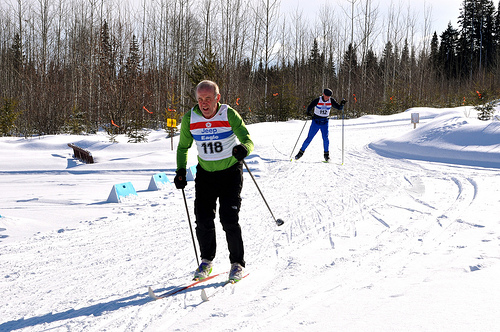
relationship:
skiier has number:
[178, 81, 256, 287] [200, 142, 224, 153]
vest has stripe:
[189, 103, 240, 162] [188, 120, 232, 130]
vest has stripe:
[189, 103, 240, 162] [190, 130, 234, 141]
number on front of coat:
[200, 142, 224, 153] [175, 109, 253, 169]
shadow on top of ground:
[1, 269, 237, 327] [0, 107, 500, 329]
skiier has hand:
[178, 81, 256, 287] [231, 144, 249, 162]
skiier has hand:
[178, 81, 256, 287] [173, 167, 187, 189]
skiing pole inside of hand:
[241, 158, 284, 226] [231, 144, 249, 162]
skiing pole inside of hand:
[181, 187, 200, 267] [173, 167, 187, 189]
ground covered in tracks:
[0, 107, 500, 329] [0, 160, 474, 331]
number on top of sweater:
[200, 142, 224, 153] [175, 109, 253, 169]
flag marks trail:
[110, 120, 121, 128] [0, 108, 488, 332]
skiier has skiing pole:
[178, 81, 256, 287] [241, 158, 284, 226]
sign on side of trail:
[410, 113, 421, 125] [0, 108, 488, 332]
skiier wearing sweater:
[178, 81, 256, 287] [175, 109, 253, 169]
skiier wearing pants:
[178, 81, 256, 287] [194, 168, 246, 267]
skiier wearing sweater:
[295, 86, 345, 160] [306, 97, 343, 122]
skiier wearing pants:
[295, 86, 345, 160] [298, 119, 332, 154]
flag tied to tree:
[353, 94, 359, 104] [337, 44, 364, 120]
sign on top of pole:
[167, 118, 175, 128] [170, 128, 174, 152]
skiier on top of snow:
[178, 81, 256, 287] [0, 107, 500, 329]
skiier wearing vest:
[178, 81, 256, 287] [189, 103, 240, 162]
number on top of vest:
[200, 142, 224, 153] [189, 103, 240, 162]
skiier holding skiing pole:
[178, 81, 256, 287] [241, 158, 284, 226]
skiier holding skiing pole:
[178, 81, 256, 287] [181, 187, 200, 267]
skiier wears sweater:
[178, 81, 256, 287] [175, 109, 253, 169]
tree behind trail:
[311, 39, 321, 117] [0, 108, 488, 332]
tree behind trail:
[337, 44, 364, 120] [0, 108, 488, 332]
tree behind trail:
[356, 53, 386, 118] [0, 108, 488, 332]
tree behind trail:
[380, 44, 400, 114] [0, 108, 488, 332]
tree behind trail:
[400, 44, 410, 105] [0, 108, 488, 332]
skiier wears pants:
[178, 81, 256, 287] [194, 168, 246, 267]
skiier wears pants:
[295, 86, 345, 160] [298, 119, 332, 154]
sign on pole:
[167, 118, 175, 128] [170, 128, 174, 152]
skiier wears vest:
[178, 81, 256, 287] [189, 103, 240, 162]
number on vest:
[200, 142, 224, 153] [189, 103, 240, 162]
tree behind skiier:
[311, 39, 321, 117] [178, 81, 256, 287]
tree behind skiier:
[337, 44, 364, 120] [178, 81, 256, 287]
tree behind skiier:
[356, 53, 386, 118] [178, 81, 256, 287]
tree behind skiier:
[380, 44, 400, 114] [178, 81, 256, 287]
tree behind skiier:
[400, 44, 410, 105] [178, 81, 256, 287]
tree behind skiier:
[311, 39, 321, 117] [295, 86, 345, 160]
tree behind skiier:
[337, 44, 364, 120] [295, 86, 345, 160]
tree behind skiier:
[356, 53, 386, 118] [295, 86, 345, 160]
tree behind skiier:
[380, 44, 400, 114] [295, 86, 345, 160]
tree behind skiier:
[400, 44, 410, 105] [295, 86, 345, 160]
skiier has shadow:
[178, 81, 256, 287] [1, 269, 237, 327]